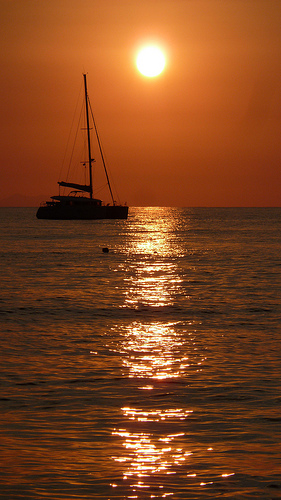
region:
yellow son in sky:
[134, 42, 166, 76]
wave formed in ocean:
[5, 303, 272, 316]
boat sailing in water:
[37, 73, 129, 220]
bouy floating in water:
[102, 245, 108, 253]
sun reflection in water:
[123, 206, 177, 491]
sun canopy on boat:
[58, 181, 94, 191]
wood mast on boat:
[84, 74, 94, 198]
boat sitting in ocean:
[39, 201, 131, 217]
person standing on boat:
[106, 201, 111, 206]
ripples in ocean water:
[3, 331, 280, 372]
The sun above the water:
[132, 40, 171, 85]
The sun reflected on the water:
[129, 204, 194, 493]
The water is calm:
[16, 367, 95, 487]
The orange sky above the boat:
[116, 99, 274, 190]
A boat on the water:
[36, 75, 129, 220]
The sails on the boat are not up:
[58, 72, 115, 197]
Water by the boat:
[45, 221, 185, 241]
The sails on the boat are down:
[57, 177, 92, 192]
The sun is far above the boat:
[130, 36, 171, 82]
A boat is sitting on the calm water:
[42, 71, 129, 217]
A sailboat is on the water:
[20, 44, 161, 303]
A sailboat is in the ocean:
[25, 48, 174, 313]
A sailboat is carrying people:
[25, 40, 213, 294]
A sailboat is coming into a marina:
[19, 54, 190, 304]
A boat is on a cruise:
[25, 43, 188, 314]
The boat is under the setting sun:
[26, 26, 218, 307]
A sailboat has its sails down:
[23, 34, 167, 284]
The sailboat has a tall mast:
[29, 48, 192, 304]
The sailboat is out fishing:
[24, 40, 210, 314]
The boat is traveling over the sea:
[26, 26, 208, 316]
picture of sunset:
[3, 2, 279, 498]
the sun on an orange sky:
[101, 2, 275, 198]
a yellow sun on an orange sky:
[115, 3, 279, 206]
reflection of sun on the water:
[101, 202, 280, 498]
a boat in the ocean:
[30, 70, 133, 226]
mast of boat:
[77, 68, 99, 198]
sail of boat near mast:
[48, 172, 105, 202]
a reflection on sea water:
[115, 202, 210, 499]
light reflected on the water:
[118, 202, 225, 499]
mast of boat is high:
[31, 65, 135, 224]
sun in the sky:
[116, 38, 181, 87]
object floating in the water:
[96, 243, 125, 259]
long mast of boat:
[77, 70, 96, 200]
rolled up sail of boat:
[59, 174, 94, 193]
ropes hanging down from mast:
[89, 101, 117, 204]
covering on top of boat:
[52, 190, 91, 202]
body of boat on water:
[33, 203, 133, 219]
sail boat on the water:
[33, 68, 124, 230]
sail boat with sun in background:
[20, 37, 192, 269]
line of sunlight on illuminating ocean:
[111, 200, 196, 475]